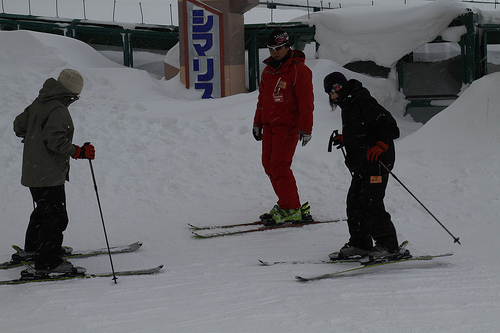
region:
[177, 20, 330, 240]
a man wearing red on snow skis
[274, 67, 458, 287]
a person wearing black on skis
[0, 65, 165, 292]
a person wearing brown and black on snow skis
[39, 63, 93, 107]
a head of person wearing a stocking cap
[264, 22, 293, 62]
a head of a person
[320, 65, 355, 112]
the head of a person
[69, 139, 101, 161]
a mitten on a hand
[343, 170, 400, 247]
a pair black snow pants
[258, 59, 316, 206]
a red winter coat and snow pants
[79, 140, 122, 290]
a hand holding a ski pole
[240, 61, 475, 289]
People on their skis.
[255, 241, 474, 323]
Skis on the snow.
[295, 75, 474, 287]
Man holding a ski pole.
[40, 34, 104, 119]
Man with a white hat.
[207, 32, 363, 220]
Man in a red snow suit.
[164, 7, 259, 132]
Sign in the background.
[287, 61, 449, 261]
Man in a black snowsuit.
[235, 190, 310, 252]
Snow boots on the skis.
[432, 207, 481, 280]
Tip of the ski pole.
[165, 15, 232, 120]
White and blue sign.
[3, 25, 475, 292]
Three people on skis.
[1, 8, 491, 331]
White snow covering the ground.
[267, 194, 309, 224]
Lime green ski boots.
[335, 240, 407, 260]
Grey ski boots.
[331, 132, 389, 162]
Red and black ski gloves.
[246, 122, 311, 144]
White and grey winter gloves.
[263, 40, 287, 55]
A pair of white framed sunglasses.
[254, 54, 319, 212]
A red snow suit.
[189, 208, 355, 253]
A pair of skis.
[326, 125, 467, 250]
A pair of ski poles.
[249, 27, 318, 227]
skier in red snow suit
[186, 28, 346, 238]
snow skier wearing skis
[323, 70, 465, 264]
skier holding snow poles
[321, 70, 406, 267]
skier in all black clothing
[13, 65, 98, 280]
skier in gray ski jacket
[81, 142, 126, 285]
ski pole held by skier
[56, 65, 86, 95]
tan stocking cap on skier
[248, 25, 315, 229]
skier wearing goggles and cap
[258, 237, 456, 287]
snow skis on white snow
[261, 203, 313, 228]
yellow and black bindings on skis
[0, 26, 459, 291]
People are on skis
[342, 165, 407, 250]
Woman is wearing pants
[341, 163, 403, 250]
Woman is wearing black pants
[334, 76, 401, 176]
Woman is wearing a jacket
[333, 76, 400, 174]
Woman is wearing a black jacket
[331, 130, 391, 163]
Woman is wearing gloves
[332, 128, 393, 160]
Woman is wearing red gloves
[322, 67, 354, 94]
Woman is wearing a hat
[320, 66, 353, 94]
Woman is wearing a black hat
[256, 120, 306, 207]
Man is wearing red pants